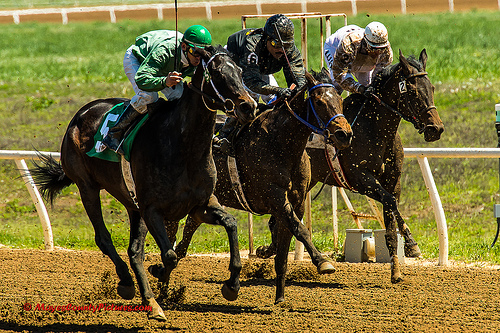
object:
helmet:
[362, 19, 389, 50]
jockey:
[317, 20, 397, 95]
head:
[360, 20, 390, 60]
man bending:
[95, 24, 219, 156]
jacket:
[225, 27, 307, 96]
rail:
[0, 148, 499, 266]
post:
[296, 17, 309, 72]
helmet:
[261, 12, 295, 46]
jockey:
[209, 14, 308, 153]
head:
[259, 12, 294, 61]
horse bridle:
[303, 89, 328, 128]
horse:
[250, 48, 446, 285]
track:
[0, 246, 499, 333]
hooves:
[136, 295, 170, 324]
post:
[416, 156, 448, 267]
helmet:
[177, 24, 213, 50]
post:
[104, 10, 118, 24]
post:
[203, 7, 214, 22]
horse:
[143, 65, 355, 310]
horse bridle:
[322, 112, 345, 133]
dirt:
[0, 245, 499, 332]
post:
[10, 157, 57, 252]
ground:
[0, 0, 499, 333]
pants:
[121, 44, 186, 115]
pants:
[239, 71, 279, 109]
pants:
[318, 41, 375, 96]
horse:
[13, 42, 260, 325]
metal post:
[328, 179, 340, 255]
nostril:
[339, 131, 348, 139]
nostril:
[350, 133, 355, 143]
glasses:
[181, 45, 210, 59]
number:
[90, 110, 117, 155]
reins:
[203, 75, 225, 103]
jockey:
[100, 23, 214, 157]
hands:
[164, 69, 188, 87]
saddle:
[95, 97, 167, 155]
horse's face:
[308, 88, 358, 151]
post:
[13, 14, 21, 27]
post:
[154, 8, 166, 23]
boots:
[96, 102, 142, 158]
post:
[327, 184, 343, 257]